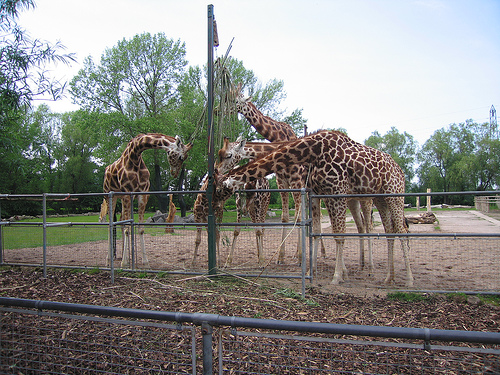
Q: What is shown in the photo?
A: Animals.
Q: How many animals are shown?
A: Six.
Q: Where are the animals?
A: Zoo.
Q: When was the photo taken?
A: Daytime.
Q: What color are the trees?
A: Green.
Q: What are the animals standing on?
A: Dirt.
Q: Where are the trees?
A: Background.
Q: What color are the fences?
A: Gray.